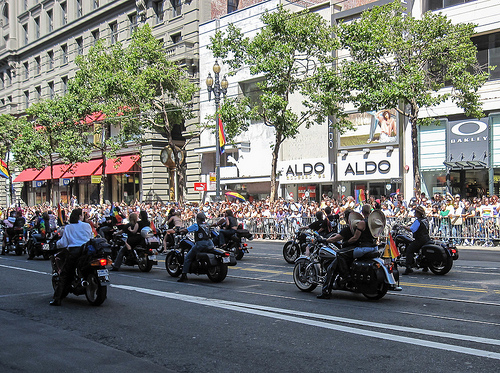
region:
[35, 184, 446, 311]
group of people riding motorcycles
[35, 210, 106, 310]
person on motorcycle without helmet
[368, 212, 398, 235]
large brown hat behind person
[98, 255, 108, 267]
back red light of cycle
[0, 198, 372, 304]
group of motorists on street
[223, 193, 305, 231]
large crowd of people on street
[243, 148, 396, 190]
store signs on buildings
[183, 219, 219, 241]
black leather jacket on man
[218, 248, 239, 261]
back light of cycle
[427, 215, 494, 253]
silver metal fence by side walk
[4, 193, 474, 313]
Parade of motorcycles on the street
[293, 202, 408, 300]
bike riders with sombreros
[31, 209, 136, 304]
Man in a white shirt on a motorcycle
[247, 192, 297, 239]
Spectators watching a parade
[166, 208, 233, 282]
Motorcyclist in a parade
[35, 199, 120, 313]
Motorcyclist in a parade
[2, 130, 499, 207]
Businesses on a city street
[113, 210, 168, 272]
A man and a woman on a motorcycle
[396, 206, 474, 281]
A woman wearing a cowboy hat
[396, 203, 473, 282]
A woman wearing a cowboy hat on a motorcycle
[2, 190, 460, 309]
People are riding motorcycles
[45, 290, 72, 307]
Woman is wearing shoes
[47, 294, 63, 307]
Woman is wearing black shoes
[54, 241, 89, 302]
Woman is wearing pants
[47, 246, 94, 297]
Woman is wearing black pants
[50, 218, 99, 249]
Woman is wearing a shirt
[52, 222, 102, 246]
Woman is wearing a white shirt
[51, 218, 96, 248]
Woman is wearing a long sleeved shirt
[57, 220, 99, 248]
Woman is wearing a white long sleeved shirt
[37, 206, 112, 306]
Woman is riding a motorcycle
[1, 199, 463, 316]
people riding motorcycles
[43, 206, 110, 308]
a person on the motorcycle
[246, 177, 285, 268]
spectators behind the fence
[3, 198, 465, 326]
motorcycles going in the same direction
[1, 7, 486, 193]
line of trees in the background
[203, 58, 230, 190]
post of lights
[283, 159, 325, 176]
a sign on the building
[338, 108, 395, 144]
a print on the wall of the building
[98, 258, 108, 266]
a light on the motorcycle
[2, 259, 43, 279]
a solid white line on the road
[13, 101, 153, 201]
this establishment has red awnings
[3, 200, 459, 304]
a parade of motorcycles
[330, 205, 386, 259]
this motorcycle couple has Mexican style hats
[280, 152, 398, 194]
this store is called Aldo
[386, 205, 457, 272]
this biker is wearing a leather vest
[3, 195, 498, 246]
a big crowd watches the motorcycles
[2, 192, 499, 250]
barriers were set up in advance to keep the crowds back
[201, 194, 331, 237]
the clothes and sun visors indicate a warm sunny day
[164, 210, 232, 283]
this biker is wearing a leather vest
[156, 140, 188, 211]
a clock overlooking the street